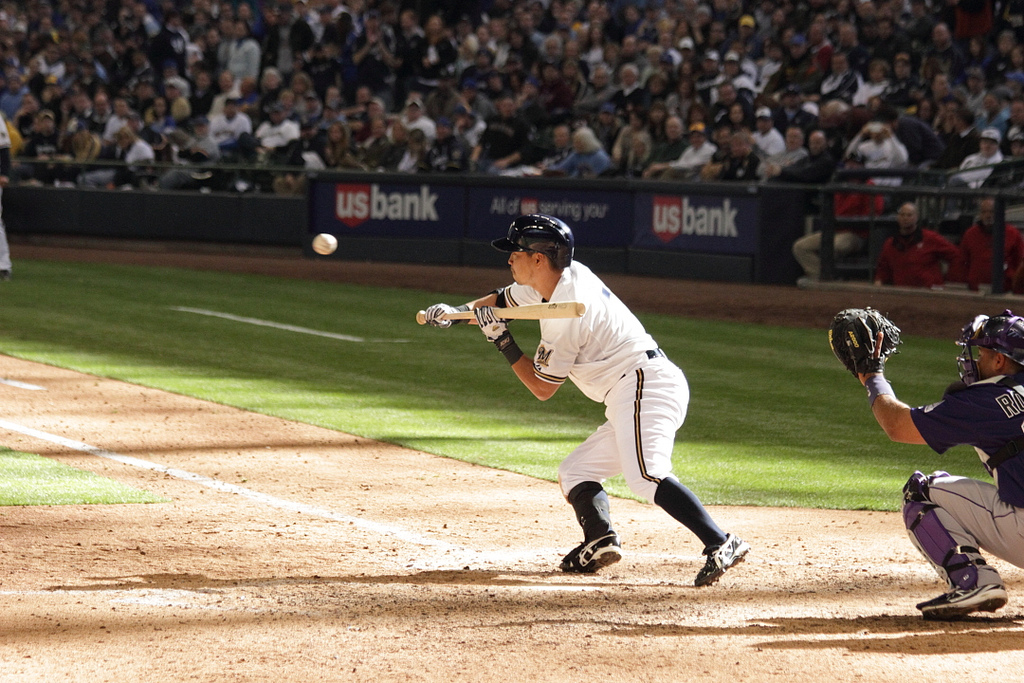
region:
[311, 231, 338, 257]
the baseball is in motion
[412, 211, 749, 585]
the player is holding the bat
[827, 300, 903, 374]
the baseball glove is black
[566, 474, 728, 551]
the socks are black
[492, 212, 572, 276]
the hard hat is black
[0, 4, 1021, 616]
the spectators looking at the baseball player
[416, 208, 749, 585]
the baseball player is wearing gloves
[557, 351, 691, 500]
the baseball pants are white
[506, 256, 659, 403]
the baseball jersey is white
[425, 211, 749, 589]
batter wearing white uniform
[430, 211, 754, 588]
batter wearing black batting helmet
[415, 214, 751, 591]
batter holding baseball bat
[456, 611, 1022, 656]
shadow of catcher on ground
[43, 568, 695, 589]
shadow of batter on ground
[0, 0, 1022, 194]
fans sitting in baseball stadium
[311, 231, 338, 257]
baseball in air near batter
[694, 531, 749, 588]
batter's left baseball cleat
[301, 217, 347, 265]
Baseball in mid-air approaching batter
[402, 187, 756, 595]
Baseball batter with white uniform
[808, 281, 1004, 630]
Baseball catcher with blue and gray uniform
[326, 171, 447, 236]
Advertising on wall in baseball field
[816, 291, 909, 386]
Catcher's mitt on left hand of catcher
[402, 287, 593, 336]
Baseball bat held horizontally by batter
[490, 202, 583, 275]
Batter's helmet on batter's head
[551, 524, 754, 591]
Cleats on batter's feet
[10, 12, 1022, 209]
Baseball fans at a ball game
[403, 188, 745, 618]
man wearing a helmet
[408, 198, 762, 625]
man holding a bat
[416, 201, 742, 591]
man wearing white shirt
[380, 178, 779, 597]
man wearing white pants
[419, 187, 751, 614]
man wearing black socks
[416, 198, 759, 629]
man wearing black shoes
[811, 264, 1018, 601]
man holding a glove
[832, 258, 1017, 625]
man wearing black shirt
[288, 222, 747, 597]
man hitting a ball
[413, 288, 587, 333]
a long wooden baseball bat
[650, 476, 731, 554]
a man's long black sock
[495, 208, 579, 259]
a black baseball helmet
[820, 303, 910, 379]
a large black baseball glove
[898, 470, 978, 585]
a long leg pad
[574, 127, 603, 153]
a person's long gray hair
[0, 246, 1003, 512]
a green section of grass